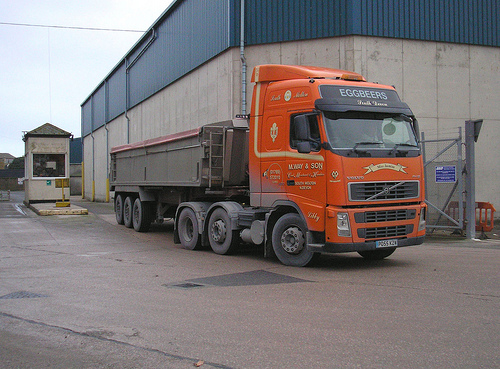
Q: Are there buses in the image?
A: No, there are no buses.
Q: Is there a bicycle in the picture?
A: No, there are no bicycles.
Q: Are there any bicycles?
A: No, there are no bicycles.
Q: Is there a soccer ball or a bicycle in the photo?
A: No, there are no bicycles or soccer balls.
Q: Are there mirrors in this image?
A: Yes, there is a mirror.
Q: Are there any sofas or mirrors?
A: Yes, there is a mirror.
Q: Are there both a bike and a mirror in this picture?
A: No, there is a mirror but no bikes.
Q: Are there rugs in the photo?
A: No, there are no rugs.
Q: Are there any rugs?
A: No, there are no rugs.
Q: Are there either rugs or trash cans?
A: No, there are no rugs or trash cans.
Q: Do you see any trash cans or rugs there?
A: No, there are no rugs or trash cans.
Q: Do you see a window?
A: Yes, there is a window.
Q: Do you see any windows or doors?
A: Yes, there is a window.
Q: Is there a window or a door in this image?
A: Yes, there is a window.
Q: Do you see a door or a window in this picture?
A: Yes, there is a window.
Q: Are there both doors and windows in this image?
A: Yes, there are both a window and a door.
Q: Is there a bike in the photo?
A: No, there are no bikes.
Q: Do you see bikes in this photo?
A: No, there are no bikes.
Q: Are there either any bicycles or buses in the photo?
A: No, there are no bicycles or buses.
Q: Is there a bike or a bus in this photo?
A: No, there are no bikes or buses.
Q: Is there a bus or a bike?
A: No, there are no bikes or buses.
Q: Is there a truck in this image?
A: Yes, there is a truck.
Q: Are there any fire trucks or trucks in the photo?
A: Yes, there is a truck.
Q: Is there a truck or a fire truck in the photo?
A: Yes, there is a truck.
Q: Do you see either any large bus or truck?
A: Yes, there is a large truck.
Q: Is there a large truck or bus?
A: Yes, there is a large truck.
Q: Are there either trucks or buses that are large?
A: Yes, the truck is large.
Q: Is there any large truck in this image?
A: Yes, there is a large truck.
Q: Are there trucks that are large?
A: Yes, there is a truck that is large.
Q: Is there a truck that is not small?
A: Yes, there is a large truck.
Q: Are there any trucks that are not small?
A: Yes, there is a large truck.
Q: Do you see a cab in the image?
A: No, there are no taxis.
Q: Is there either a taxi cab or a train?
A: No, there are no taxis or trains.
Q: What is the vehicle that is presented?
A: The vehicle is a truck.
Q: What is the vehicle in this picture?
A: The vehicle is a truck.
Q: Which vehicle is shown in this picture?
A: The vehicle is a truck.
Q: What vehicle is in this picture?
A: The vehicle is a truck.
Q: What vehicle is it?
A: The vehicle is a truck.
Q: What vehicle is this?
A: This is a truck.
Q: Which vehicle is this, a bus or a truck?
A: This is a truck.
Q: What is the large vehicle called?
A: The vehicle is a truck.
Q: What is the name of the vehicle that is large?
A: The vehicle is a truck.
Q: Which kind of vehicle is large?
A: The vehicle is a truck.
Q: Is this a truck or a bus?
A: This is a truck.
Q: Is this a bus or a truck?
A: This is a truck.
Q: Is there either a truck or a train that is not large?
A: No, there is a truck but it is large.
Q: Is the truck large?
A: Yes, the truck is large.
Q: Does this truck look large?
A: Yes, the truck is large.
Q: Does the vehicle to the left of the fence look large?
A: Yes, the truck is large.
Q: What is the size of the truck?
A: The truck is large.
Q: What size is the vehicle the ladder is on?
A: The truck is large.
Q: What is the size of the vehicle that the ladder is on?
A: The truck is large.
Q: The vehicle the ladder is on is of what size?
A: The truck is large.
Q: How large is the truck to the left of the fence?
A: The truck is large.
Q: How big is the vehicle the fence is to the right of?
A: The truck is large.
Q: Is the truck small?
A: No, the truck is large.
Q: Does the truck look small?
A: No, the truck is large.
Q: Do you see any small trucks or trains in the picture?
A: No, there is a truck but it is large.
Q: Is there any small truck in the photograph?
A: No, there is a truck but it is large.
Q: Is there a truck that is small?
A: No, there is a truck but it is large.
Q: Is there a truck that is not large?
A: No, there is a truck but it is large.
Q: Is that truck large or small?
A: The truck is large.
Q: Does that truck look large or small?
A: The truck is large.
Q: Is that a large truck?
A: Yes, that is a large truck.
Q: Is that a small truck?
A: No, that is a large truck.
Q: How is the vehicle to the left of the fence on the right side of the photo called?
A: The vehicle is a truck.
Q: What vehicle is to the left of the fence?
A: The vehicle is a truck.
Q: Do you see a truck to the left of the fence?
A: Yes, there is a truck to the left of the fence.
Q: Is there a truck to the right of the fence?
A: No, the truck is to the left of the fence.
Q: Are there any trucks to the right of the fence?
A: No, the truck is to the left of the fence.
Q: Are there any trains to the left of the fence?
A: No, there is a truck to the left of the fence.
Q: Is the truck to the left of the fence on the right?
A: Yes, the truck is to the left of the fence.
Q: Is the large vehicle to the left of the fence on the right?
A: Yes, the truck is to the left of the fence.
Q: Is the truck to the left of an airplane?
A: No, the truck is to the left of the fence.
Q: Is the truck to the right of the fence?
A: No, the truck is to the left of the fence.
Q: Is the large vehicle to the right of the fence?
A: No, the truck is to the left of the fence.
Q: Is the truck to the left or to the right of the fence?
A: The truck is to the left of the fence.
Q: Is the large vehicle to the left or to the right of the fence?
A: The truck is to the left of the fence.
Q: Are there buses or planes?
A: No, there are no buses or planes.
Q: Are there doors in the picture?
A: Yes, there is a door.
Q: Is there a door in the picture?
A: Yes, there is a door.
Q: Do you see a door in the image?
A: Yes, there is a door.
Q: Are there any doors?
A: Yes, there is a door.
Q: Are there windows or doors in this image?
A: Yes, there is a door.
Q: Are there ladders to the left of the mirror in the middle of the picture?
A: Yes, there is a ladder to the left of the mirror.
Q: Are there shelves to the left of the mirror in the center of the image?
A: No, there is a ladder to the left of the mirror.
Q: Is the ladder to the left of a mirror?
A: Yes, the ladder is to the left of a mirror.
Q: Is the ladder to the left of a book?
A: No, the ladder is to the left of a mirror.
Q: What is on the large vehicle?
A: The ladder is on the truck.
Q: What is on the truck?
A: The ladder is on the truck.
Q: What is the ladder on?
A: The ladder is on the truck.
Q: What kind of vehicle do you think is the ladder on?
A: The ladder is on the truck.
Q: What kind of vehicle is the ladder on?
A: The ladder is on the truck.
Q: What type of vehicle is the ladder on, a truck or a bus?
A: The ladder is on a truck.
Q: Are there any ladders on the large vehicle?
A: Yes, there is a ladder on the truck.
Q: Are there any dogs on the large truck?
A: No, there is a ladder on the truck.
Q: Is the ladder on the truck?
A: Yes, the ladder is on the truck.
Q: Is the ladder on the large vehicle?
A: Yes, the ladder is on the truck.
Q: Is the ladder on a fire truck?
A: No, the ladder is on the truck.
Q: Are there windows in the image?
A: Yes, there is a window.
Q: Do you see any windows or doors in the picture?
A: Yes, there is a window.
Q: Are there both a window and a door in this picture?
A: Yes, there are both a window and a door.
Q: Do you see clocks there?
A: No, there are no clocks.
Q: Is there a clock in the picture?
A: No, there are no clocks.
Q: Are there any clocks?
A: No, there are no clocks.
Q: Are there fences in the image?
A: Yes, there is a fence.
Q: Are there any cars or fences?
A: Yes, there is a fence.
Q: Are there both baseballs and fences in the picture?
A: No, there is a fence but no baseballs.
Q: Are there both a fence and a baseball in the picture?
A: No, there is a fence but no baseballs.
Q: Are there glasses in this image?
A: No, there are no glasses.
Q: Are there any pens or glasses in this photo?
A: No, there are no glasses or pens.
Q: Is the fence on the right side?
A: Yes, the fence is on the right of the image.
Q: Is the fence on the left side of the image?
A: No, the fence is on the right of the image.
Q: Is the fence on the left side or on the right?
A: The fence is on the right of the image.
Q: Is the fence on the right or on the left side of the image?
A: The fence is on the right of the image.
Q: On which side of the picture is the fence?
A: The fence is on the right of the image.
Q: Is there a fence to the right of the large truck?
A: Yes, there is a fence to the right of the truck.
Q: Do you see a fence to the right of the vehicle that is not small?
A: Yes, there is a fence to the right of the truck.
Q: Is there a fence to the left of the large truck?
A: No, the fence is to the right of the truck.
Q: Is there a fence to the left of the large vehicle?
A: No, the fence is to the right of the truck.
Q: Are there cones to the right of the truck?
A: No, there is a fence to the right of the truck.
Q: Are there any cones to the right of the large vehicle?
A: No, there is a fence to the right of the truck.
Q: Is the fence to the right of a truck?
A: Yes, the fence is to the right of a truck.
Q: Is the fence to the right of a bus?
A: No, the fence is to the right of a truck.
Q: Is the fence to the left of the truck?
A: No, the fence is to the right of the truck.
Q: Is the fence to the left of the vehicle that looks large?
A: No, the fence is to the right of the truck.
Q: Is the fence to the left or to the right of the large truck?
A: The fence is to the right of the truck.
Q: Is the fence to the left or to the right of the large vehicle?
A: The fence is to the right of the truck.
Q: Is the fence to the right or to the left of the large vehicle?
A: The fence is to the right of the truck.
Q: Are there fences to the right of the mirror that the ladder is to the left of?
A: Yes, there is a fence to the right of the mirror.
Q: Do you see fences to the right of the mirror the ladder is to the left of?
A: Yes, there is a fence to the right of the mirror.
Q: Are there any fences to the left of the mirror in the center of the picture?
A: No, the fence is to the right of the mirror.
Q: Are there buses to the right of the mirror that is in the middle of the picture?
A: No, there is a fence to the right of the mirror.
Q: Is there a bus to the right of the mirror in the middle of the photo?
A: No, there is a fence to the right of the mirror.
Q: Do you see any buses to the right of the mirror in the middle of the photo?
A: No, there is a fence to the right of the mirror.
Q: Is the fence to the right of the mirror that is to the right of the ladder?
A: Yes, the fence is to the right of the mirror.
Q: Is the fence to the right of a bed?
A: No, the fence is to the right of the mirror.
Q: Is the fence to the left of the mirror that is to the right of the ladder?
A: No, the fence is to the right of the mirror.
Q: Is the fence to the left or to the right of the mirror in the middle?
A: The fence is to the right of the mirror.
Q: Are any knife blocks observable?
A: No, there are no knife blocks.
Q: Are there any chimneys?
A: No, there are no chimneys.